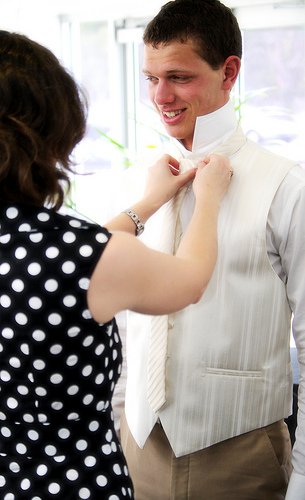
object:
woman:
[1, 29, 234, 500]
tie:
[144, 120, 247, 415]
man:
[118, 0, 305, 500]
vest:
[124, 137, 302, 460]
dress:
[0, 203, 135, 499]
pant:
[119, 415, 292, 500]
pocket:
[207, 367, 266, 379]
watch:
[120, 207, 145, 239]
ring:
[229, 168, 235, 178]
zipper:
[170, 453, 187, 499]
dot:
[44, 278, 59, 293]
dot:
[48, 312, 62, 327]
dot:
[61, 260, 75, 275]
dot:
[61, 294, 77, 308]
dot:
[44, 244, 60, 259]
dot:
[49, 373, 64, 386]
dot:
[78, 244, 93, 258]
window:
[56, 14, 127, 160]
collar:
[191, 95, 239, 157]